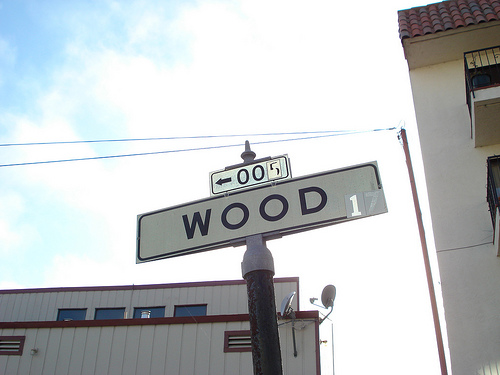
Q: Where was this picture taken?
A: Wood street.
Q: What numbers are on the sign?
A: 005.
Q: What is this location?
A: 005 Wood st.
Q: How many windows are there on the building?
A: Four.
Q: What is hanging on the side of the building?
A: Dishes.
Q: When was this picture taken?
A: Daytime.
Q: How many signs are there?
A: One.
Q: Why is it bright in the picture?
A: Sun.